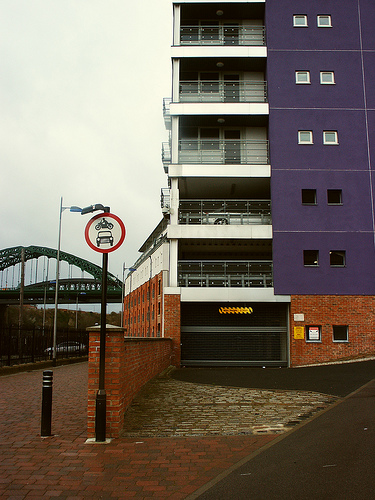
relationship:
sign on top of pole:
[85, 214, 126, 253] [96, 252, 109, 443]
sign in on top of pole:
[85, 214, 126, 253] [96, 252, 109, 443]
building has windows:
[123, 5, 372, 363] [294, 13, 332, 27]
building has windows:
[123, 5, 372, 363] [294, 70, 334, 84]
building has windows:
[123, 5, 372, 363] [296, 130, 338, 144]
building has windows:
[123, 5, 372, 363] [303, 191, 342, 206]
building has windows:
[123, 5, 372, 363] [305, 251, 346, 265]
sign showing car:
[85, 214, 126, 253] [96, 231, 114, 248]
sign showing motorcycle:
[85, 214, 126, 253] [96, 219, 114, 231]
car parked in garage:
[198, 207, 271, 224] [176, 177, 292, 367]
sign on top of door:
[218, 306, 254, 315] [180, 331, 289, 363]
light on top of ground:
[51, 196, 82, 363] [4, 362, 284, 494]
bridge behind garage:
[2, 246, 123, 304] [2, 325, 87, 373]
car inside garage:
[198, 207, 271, 224] [176, 177, 292, 367]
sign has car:
[85, 214, 126, 253] [96, 231, 114, 248]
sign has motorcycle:
[85, 214, 126, 253] [96, 219, 114, 231]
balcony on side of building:
[161, 98, 173, 130] [123, 5, 372, 363]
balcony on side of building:
[162, 142, 172, 163] [123, 5, 372, 363]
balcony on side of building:
[160, 186, 170, 215] [123, 5, 372, 363]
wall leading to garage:
[85, 327, 174, 444] [176, 177, 292, 367]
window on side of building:
[293, 16, 309, 28] [123, 5, 372, 363]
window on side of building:
[318, 14, 331, 29] [123, 5, 372, 363]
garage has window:
[176, 177, 292, 367] [305, 325, 323, 341]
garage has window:
[2, 325, 87, 373] [333, 325, 347, 342]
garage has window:
[2, 325, 87, 373] [303, 248, 321, 266]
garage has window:
[2, 325, 87, 373] [329, 249, 344, 266]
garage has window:
[2, 325, 87, 373] [303, 188, 317, 204]